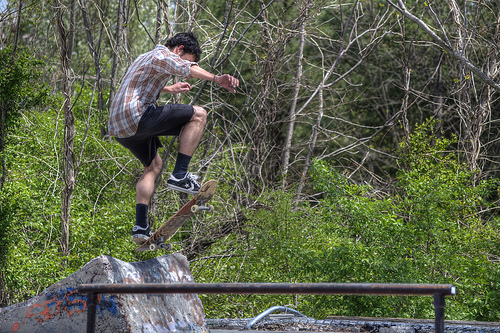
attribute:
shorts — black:
[111, 99, 193, 177]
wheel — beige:
[146, 241, 161, 254]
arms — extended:
[190, 67, 288, 109]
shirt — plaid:
[86, 29, 174, 119]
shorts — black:
[115, 106, 199, 156]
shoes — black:
[132, 142, 198, 235]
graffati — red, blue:
[9, 289, 123, 331]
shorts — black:
[92, 95, 189, 175]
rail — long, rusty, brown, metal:
[75, 281, 450, 331]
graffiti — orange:
[8, 282, 100, 329]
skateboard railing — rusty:
[74, 278, 454, 329]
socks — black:
[122, 146, 194, 237]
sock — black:
[118, 134, 219, 182]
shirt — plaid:
[102, 44, 194, 139]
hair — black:
[163, 27, 204, 63]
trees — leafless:
[218, 0, 402, 183]